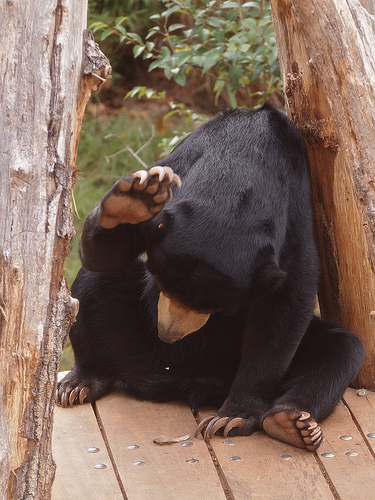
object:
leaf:
[162, 109, 180, 123]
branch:
[99, 118, 155, 163]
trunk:
[269, 0, 374, 391]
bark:
[284, 72, 341, 153]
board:
[93, 389, 228, 499]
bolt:
[134, 461, 145, 466]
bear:
[53, 100, 365, 452]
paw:
[100, 165, 182, 229]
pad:
[99, 192, 153, 228]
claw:
[133, 170, 148, 186]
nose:
[158, 321, 184, 344]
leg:
[260, 316, 364, 453]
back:
[155, 100, 308, 170]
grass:
[64, 111, 142, 292]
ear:
[254, 261, 289, 298]